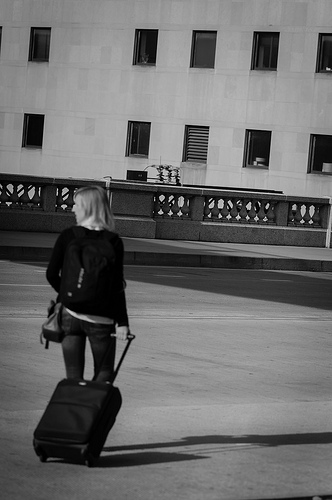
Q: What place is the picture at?
A: It is at the street.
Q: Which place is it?
A: It is a street.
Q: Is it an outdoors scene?
A: Yes, it is outdoors.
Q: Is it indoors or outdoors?
A: It is outdoors.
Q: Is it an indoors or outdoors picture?
A: It is outdoors.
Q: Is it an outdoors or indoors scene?
A: It is outdoors.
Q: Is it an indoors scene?
A: No, it is outdoors.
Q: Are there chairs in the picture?
A: No, there are no chairs.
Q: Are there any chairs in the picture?
A: No, there are no chairs.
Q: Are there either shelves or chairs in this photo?
A: No, there are no chairs or shelves.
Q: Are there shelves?
A: No, there are no shelves.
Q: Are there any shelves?
A: No, there are no shelves.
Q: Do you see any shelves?
A: No, there are no shelves.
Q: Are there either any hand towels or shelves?
A: No, there are no shelves or hand towels.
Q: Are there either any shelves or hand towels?
A: No, there are no shelves or hand towels.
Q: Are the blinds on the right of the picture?
A: Yes, the blinds are on the right of the image.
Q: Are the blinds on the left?
A: No, the blinds are on the right of the image.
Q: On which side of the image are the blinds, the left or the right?
A: The blinds are on the right of the image.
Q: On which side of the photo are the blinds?
A: The blinds are on the right of the image.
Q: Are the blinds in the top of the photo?
A: Yes, the blinds are in the top of the image.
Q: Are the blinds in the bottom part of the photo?
A: No, the blinds are in the top of the image.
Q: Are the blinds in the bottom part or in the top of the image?
A: The blinds are in the top of the image.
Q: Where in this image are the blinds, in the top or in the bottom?
A: The blinds are in the top of the image.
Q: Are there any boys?
A: No, there are no boys.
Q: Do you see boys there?
A: No, there are no boys.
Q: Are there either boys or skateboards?
A: No, there are no boys or skateboards.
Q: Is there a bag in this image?
A: Yes, there is a bag.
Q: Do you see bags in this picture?
A: Yes, there is a bag.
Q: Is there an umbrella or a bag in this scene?
A: Yes, there is a bag.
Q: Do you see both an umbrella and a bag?
A: No, there is a bag but no umbrellas.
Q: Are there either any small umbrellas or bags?
A: Yes, there is a small bag.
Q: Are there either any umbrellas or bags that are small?
A: Yes, the bag is small.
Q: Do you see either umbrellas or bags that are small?
A: Yes, the bag is small.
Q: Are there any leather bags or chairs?
A: Yes, there is a leather bag.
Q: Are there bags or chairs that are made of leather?
A: Yes, the bag is made of leather.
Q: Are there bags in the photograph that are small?
A: Yes, there is a small bag.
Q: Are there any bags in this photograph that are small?
A: Yes, there is a bag that is small.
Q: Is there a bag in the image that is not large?
A: Yes, there is a small bag.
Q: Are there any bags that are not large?
A: Yes, there is a small bag.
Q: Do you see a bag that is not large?
A: Yes, there is a small bag.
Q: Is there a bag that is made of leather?
A: Yes, there is a bag that is made of leather.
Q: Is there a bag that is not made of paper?
A: Yes, there is a bag that is made of leather.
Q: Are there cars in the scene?
A: No, there are no cars.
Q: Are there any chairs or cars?
A: No, there are no cars or chairs.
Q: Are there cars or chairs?
A: No, there are no cars or chairs.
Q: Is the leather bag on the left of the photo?
A: Yes, the bag is on the left of the image.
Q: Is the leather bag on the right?
A: No, the bag is on the left of the image.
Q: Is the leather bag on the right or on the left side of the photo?
A: The bag is on the left of the image.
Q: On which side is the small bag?
A: The bag is on the left of the image.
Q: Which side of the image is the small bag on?
A: The bag is on the left of the image.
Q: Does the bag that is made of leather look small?
A: Yes, the bag is small.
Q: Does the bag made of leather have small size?
A: Yes, the bag is small.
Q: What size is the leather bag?
A: The bag is small.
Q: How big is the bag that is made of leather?
A: The bag is small.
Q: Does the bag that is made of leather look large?
A: No, the bag is small.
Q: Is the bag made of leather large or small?
A: The bag is small.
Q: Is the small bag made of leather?
A: Yes, the bag is made of leather.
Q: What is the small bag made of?
A: The bag is made of leather.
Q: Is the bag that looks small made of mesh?
A: No, the bag is made of leather.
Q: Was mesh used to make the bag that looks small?
A: No, the bag is made of leather.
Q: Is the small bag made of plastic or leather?
A: The bag is made of leather.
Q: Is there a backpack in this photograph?
A: Yes, there is a backpack.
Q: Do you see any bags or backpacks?
A: Yes, there is a backpack.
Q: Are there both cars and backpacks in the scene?
A: No, there is a backpack but no cars.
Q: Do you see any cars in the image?
A: No, there are no cars.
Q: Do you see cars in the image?
A: No, there are no cars.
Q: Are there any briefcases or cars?
A: No, there are no cars or briefcases.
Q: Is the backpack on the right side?
A: No, the backpack is on the left of the image.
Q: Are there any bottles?
A: No, there are no bottles.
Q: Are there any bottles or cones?
A: No, there are no bottles or cones.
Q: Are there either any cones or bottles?
A: No, there are no bottles or cones.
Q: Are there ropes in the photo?
A: No, there are no ropes.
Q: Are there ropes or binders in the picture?
A: No, there are no ropes or binders.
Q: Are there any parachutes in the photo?
A: No, there are no parachutes.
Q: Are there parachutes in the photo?
A: No, there are no parachutes.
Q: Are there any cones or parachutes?
A: No, there are no parachutes or cones.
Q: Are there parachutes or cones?
A: No, there are no parachutes or cones.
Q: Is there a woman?
A: Yes, there is a woman.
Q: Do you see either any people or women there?
A: Yes, there is a woman.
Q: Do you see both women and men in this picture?
A: No, there is a woman but no men.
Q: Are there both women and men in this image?
A: No, there is a woman but no men.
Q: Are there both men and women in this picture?
A: No, there is a woman but no men.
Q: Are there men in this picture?
A: No, there are no men.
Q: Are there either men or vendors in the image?
A: No, there are no men or vendors.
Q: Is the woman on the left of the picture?
A: Yes, the woman is on the left of the image.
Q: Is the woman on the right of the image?
A: No, the woman is on the left of the image.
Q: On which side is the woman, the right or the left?
A: The woman is on the left of the image.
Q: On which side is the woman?
A: The woman is on the left of the image.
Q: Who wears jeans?
A: The woman wears jeans.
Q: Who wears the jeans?
A: The woman wears jeans.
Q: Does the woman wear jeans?
A: Yes, the woman wears jeans.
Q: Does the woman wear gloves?
A: No, the woman wears jeans.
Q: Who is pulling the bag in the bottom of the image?
A: The woman is pulling the bag.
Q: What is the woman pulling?
A: The woman is pulling the bag.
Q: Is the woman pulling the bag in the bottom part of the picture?
A: Yes, the woman is pulling the bag.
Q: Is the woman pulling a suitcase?
A: No, the woman is pulling the bag.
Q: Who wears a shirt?
A: The woman wears a shirt.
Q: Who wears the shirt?
A: The woman wears a shirt.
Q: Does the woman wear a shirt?
A: Yes, the woman wears a shirt.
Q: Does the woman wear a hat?
A: No, the woman wears a shirt.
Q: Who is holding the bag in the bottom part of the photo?
A: The woman is holding the bag.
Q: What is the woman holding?
A: The woman is holding the bag.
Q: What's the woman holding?
A: The woman is holding the bag.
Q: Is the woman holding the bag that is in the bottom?
A: Yes, the woman is holding the bag.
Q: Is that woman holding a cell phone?
A: No, the woman is holding the bag.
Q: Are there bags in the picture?
A: Yes, there is a bag.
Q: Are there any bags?
A: Yes, there is a bag.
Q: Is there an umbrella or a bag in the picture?
A: Yes, there is a bag.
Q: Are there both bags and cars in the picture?
A: No, there is a bag but no cars.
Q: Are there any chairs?
A: No, there are no chairs.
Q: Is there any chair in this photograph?
A: No, there are no chairs.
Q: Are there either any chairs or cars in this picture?
A: No, there are no chairs or cars.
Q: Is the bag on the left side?
A: Yes, the bag is on the left of the image.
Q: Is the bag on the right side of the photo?
A: No, the bag is on the left of the image.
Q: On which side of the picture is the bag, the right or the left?
A: The bag is on the left of the image.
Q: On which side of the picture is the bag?
A: The bag is on the left of the image.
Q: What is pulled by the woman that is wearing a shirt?
A: The bag is pulled by the woman.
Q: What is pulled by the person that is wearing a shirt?
A: The bag is pulled by the woman.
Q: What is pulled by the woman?
A: The bag is pulled by the woman.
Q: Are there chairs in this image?
A: No, there are no chairs.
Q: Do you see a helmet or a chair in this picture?
A: No, there are no chairs or helmets.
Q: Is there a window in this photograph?
A: Yes, there is a window.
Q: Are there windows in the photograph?
A: Yes, there is a window.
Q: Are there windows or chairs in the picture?
A: Yes, there is a window.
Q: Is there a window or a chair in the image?
A: Yes, there is a window.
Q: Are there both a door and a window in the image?
A: No, there is a window but no doors.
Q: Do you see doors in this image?
A: No, there are no doors.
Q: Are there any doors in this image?
A: No, there are no doors.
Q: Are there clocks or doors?
A: No, there are no doors or clocks.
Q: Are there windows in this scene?
A: Yes, there is a window.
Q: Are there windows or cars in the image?
A: Yes, there is a window.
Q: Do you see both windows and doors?
A: No, there is a window but no doors.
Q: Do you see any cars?
A: No, there are no cars.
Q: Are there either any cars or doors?
A: No, there are no cars or doors.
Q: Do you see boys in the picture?
A: No, there are no boys.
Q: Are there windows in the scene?
A: Yes, there is a window.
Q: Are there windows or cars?
A: Yes, there is a window.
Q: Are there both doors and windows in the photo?
A: No, there is a window but no doors.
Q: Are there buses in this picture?
A: No, there are no buses.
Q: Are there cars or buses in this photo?
A: No, there are no buses or cars.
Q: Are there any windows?
A: Yes, there is a window.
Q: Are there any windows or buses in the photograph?
A: Yes, there is a window.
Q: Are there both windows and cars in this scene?
A: No, there is a window but no cars.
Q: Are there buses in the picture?
A: No, there are no buses.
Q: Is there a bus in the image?
A: No, there are no buses.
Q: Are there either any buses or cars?
A: No, there are no buses or cars.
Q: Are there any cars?
A: No, there are no cars.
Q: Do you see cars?
A: No, there are no cars.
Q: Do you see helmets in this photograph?
A: No, there are no helmets.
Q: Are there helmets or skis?
A: No, there are no helmets or skis.